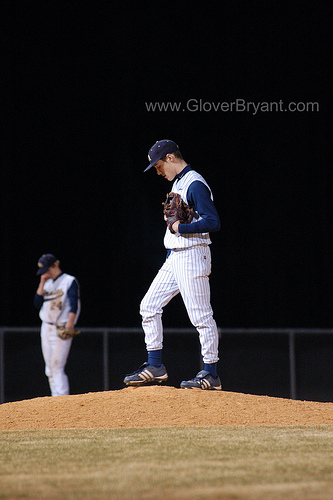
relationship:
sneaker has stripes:
[121, 363, 168, 384] [139, 368, 153, 381]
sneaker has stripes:
[178, 369, 222, 389] [196, 377, 211, 387]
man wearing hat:
[130, 134, 235, 385] [141, 135, 179, 174]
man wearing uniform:
[130, 134, 235, 385] [140, 168, 221, 367]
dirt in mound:
[2, 387, 329, 423] [0, 384, 332, 428]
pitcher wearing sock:
[120, 138, 223, 391] [144, 350, 162, 366]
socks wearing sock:
[140, 343, 219, 382] [198, 357, 221, 379]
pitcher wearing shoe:
[120, 138, 223, 391] [180, 372, 224, 390]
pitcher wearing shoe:
[120, 138, 223, 391] [124, 363, 169, 389]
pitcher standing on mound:
[120, 138, 223, 391] [0, 383, 332, 498]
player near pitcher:
[32, 251, 80, 396] [120, 138, 223, 391]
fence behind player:
[1, 328, 332, 399] [32, 251, 80, 396]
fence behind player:
[1, 328, 332, 399] [133, 129, 243, 393]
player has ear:
[133, 129, 243, 393] [165, 150, 174, 161]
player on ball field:
[32, 251, 80, 396] [2, 315, 328, 497]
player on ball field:
[133, 129, 243, 393] [2, 315, 328, 497]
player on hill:
[133, 129, 243, 393] [52, 389, 328, 428]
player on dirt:
[133, 129, 243, 393] [185, 392, 228, 421]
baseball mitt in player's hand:
[158, 193, 193, 234] [163, 215, 182, 236]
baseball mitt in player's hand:
[54, 318, 76, 339] [60, 312, 78, 334]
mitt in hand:
[155, 187, 194, 238] [60, 326, 73, 338]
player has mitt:
[32, 251, 80, 396] [155, 187, 194, 238]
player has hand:
[32, 251, 80, 396] [60, 326, 73, 338]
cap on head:
[37, 251, 62, 274] [19, 241, 76, 287]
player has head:
[32, 251, 80, 396] [19, 241, 76, 287]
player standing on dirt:
[133, 129, 243, 393] [24, 387, 325, 442]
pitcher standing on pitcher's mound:
[120, 138, 223, 391] [2, 380, 332, 424]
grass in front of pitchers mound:
[11, 426, 325, 489] [0, 383, 331, 430]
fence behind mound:
[1, 328, 332, 399] [0, 384, 332, 428]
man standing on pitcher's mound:
[130, 134, 235, 385] [0, 380, 331, 430]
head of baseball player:
[36, 254, 60, 277] [30, 255, 82, 330]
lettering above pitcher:
[134, 93, 324, 124] [122, 130, 233, 394]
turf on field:
[0, 422, 329, 498] [5, 425, 331, 497]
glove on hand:
[143, 186, 191, 240] [162, 207, 177, 233]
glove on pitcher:
[143, 186, 191, 240] [120, 138, 223, 391]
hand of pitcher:
[162, 207, 177, 233] [120, 138, 223, 391]